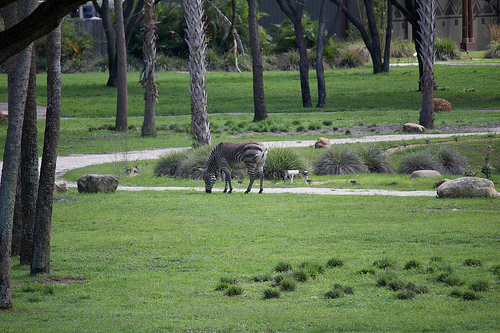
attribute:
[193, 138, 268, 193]
zebra — standing, eating, adult, grazing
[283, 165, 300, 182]
object — sticking out, white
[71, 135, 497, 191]
grass — wild, green, huge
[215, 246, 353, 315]
crab grass — little, wild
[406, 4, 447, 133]
tree — spiky, skinny, growing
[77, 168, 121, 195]
rock — big, rectangular, large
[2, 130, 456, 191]
road — gravel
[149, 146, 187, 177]
plant — puffy, growing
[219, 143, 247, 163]
stripes — white, black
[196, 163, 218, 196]
head — angled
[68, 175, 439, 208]
path — dirt, grayish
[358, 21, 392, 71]
tree trunk — tree trunk, dark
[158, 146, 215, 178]
bush — dark green, pointy, together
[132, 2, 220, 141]
palm trees — tall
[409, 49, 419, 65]
light — off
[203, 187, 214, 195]
mouth — black